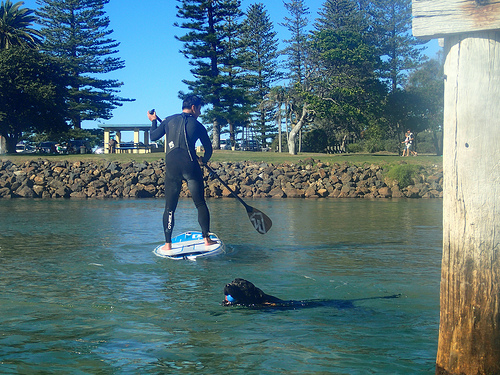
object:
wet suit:
[150, 112, 213, 242]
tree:
[172, 3, 245, 148]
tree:
[33, 0, 122, 154]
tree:
[237, 4, 280, 150]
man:
[147, 95, 217, 250]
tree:
[281, 2, 312, 154]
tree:
[378, 91, 434, 155]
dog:
[220, 277, 400, 313]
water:
[1, 279, 158, 374]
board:
[152, 230, 225, 261]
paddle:
[148, 109, 271, 235]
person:
[405, 130, 418, 157]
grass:
[4, 147, 443, 170]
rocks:
[1, 159, 440, 199]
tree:
[0, 0, 64, 154]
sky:
[116, 1, 177, 50]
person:
[401, 133, 414, 157]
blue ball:
[227, 294, 236, 302]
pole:
[436, 33, 499, 375]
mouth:
[223, 294, 239, 307]